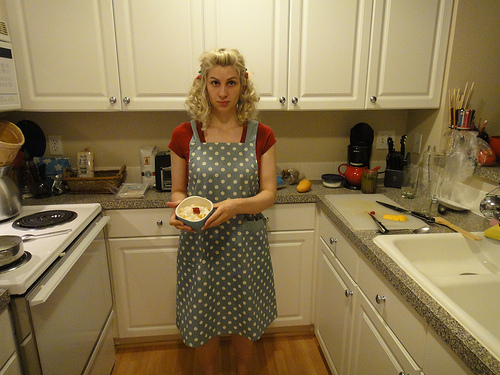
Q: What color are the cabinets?
A: White.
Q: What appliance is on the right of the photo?
A: The stove.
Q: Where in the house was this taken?
A: Kitchen.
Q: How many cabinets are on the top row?
A: Five.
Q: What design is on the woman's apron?
A: Polka dot.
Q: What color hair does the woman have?
A: Blonde.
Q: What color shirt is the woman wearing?
A: Red.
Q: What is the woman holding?
A: A bowl.